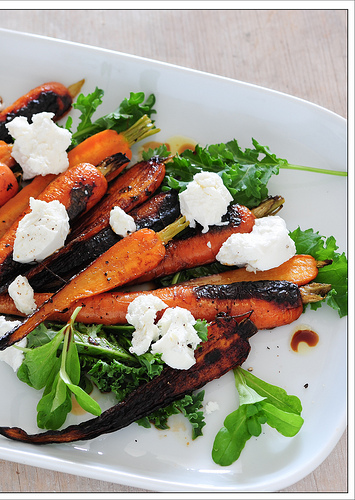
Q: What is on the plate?
A: Roasted carrots.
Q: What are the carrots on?
A: White plate.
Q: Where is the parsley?
A: On the plate with the carrots.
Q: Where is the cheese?
A: On carrots.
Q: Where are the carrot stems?
A: On carrot.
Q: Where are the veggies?
A: White table.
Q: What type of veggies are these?
A: Root veggies.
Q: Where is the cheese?
A: On the carrots.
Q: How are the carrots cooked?
A: Grilled.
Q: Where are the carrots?
A: On plate.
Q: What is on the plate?
A: Food.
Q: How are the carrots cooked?
A: Burned.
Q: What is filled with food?
A: White plate.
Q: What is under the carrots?
A: Green lettuce.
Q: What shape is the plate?
A: Retagular.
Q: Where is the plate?
A: On the table.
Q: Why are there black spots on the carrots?
A: They were burned.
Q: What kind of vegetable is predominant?
A: Carrot.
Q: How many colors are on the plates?
A: Four.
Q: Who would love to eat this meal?
A: A vegetarian.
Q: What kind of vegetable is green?
A: Lettuce.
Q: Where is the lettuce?
A: Under the carrots.